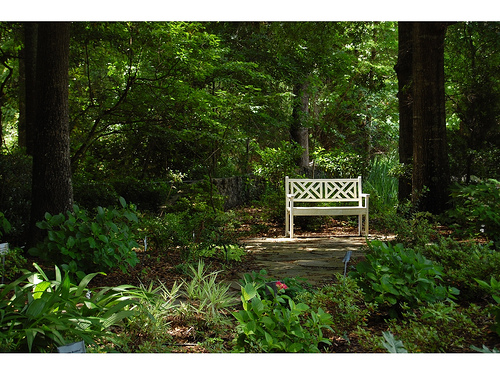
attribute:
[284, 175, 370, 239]
bench — empty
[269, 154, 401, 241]
bench — white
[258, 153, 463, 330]
bench — white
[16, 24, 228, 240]
tree — green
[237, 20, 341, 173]
tree — green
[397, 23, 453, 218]
tree — green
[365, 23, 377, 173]
tree — green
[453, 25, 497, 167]
tree — green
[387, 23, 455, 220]
brown tree — tall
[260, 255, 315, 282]
ground — brown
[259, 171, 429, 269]
bench — white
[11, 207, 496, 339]
ground — brown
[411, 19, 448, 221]
trunk — narrow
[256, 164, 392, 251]
bench — sandle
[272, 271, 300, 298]
red flower —  red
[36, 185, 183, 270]
bush — green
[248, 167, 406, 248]
bench — white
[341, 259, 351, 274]
stem — green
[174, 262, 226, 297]
bush — green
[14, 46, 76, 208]
tree trunk — brown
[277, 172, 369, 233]
bench — wooden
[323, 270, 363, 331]
weeds —  small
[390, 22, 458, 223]
tree trunk — big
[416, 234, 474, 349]
leaves —   long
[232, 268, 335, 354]
bush — low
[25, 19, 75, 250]
tree — brown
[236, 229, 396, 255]
spot — sunny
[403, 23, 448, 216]
tree — green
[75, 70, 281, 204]
tree — big